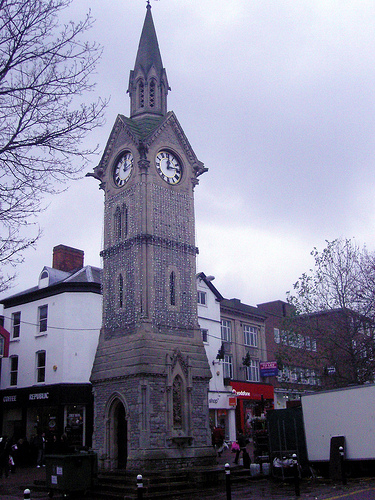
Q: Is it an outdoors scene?
A: Yes, it is outdoors.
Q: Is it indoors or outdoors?
A: It is outdoors.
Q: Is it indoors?
A: No, it is outdoors.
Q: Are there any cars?
A: No, there are no cars.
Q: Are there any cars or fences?
A: No, there are no fences or cars.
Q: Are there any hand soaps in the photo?
A: No, there are no hand soaps.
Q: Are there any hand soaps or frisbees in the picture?
A: No, there are no hand soaps or frisbees.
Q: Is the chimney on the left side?
A: Yes, the chimney is on the left of the image.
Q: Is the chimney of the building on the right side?
A: No, the chimney is on the left of the image.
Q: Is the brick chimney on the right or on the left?
A: The chimney is on the left of the image.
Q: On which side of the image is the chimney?
A: The chimney is on the left of the image.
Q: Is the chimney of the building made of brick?
A: Yes, the chimney is made of brick.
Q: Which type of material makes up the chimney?
A: The chimney is made of brick.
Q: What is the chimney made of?
A: The chimney is made of brick.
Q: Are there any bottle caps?
A: No, there are no bottle caps.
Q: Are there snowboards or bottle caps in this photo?
A: No, there are no bottle caps or snowboards.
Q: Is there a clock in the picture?
A: Yes, there is a clock.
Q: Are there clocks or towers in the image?
A: Yes, there is a clock.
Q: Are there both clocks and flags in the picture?
A: No, there is a clock but no flags.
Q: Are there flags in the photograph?
A: No, there are no flags.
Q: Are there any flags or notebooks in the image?
A: No, there are no flags or notebooks.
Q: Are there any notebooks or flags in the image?
A: No, there are no flags or notebooks.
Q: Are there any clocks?
A: Yes, there is a clock.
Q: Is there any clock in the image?
A: Yes, there is a clock.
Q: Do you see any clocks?
A: Yes, there is a clock.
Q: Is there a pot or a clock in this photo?
A: Yes, there is a clock.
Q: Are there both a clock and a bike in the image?
A: No, there is a clock but no bikes.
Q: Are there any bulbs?
A: No, there are no bulbs.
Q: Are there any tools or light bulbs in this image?
A: No, there are no light bulbs or tools.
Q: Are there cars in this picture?
A: No, there are no cars.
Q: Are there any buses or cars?
A: No, there are no cars or buses.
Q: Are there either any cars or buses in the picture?
A: No, there are no cars or buses.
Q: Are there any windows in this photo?
A: Yes, there are windows.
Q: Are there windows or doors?
A: Yes, there are windows.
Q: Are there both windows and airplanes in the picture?
A: No, there are windows but no airplanes.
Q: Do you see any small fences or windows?
A: Yes, there are small windows.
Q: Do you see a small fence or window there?
A: Yes, there are small windows.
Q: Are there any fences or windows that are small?
A: Yes, the windows are small.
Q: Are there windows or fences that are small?
A: Yes, the windows are small.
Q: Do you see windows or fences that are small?
A: Yes, the windows are small.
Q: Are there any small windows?
A: Yes, there are small windows.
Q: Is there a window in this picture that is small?
A: Yes, there are windows that are small.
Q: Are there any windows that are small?
A: Yes, there are windows that are small.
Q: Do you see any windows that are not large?
A: Yes, there are small windows.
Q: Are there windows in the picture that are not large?
A: Yes, there are small windows.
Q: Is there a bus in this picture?
A: No, there are no buses.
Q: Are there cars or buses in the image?
A: No, there are no buses or cars.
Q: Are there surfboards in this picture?
A: No, there are no surfboards.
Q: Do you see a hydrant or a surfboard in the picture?
A: No, there are no surfboards or fire hydrants.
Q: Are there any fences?
A: No, there are no fences.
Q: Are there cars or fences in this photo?
A: No, there are no fences or cars.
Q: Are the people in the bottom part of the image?
A: Yes, the people are in the bottom of the image.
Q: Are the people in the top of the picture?
A: No, the people are in the bottom of the image.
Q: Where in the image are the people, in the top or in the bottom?
A: The people are in the bottom of the image.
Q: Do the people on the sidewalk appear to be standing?
A: Yes, the people are standing.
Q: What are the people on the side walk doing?
A: The people are standing.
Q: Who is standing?
A: The people are standing.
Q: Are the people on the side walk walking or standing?
A: The people are standing.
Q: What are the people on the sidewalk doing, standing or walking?
A: The people are standing.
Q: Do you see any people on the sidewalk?
A: Yes, there are people on the sidewalk.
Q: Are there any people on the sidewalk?
A: Yes, there are people on the sidewalk.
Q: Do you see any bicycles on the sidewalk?
A: No, there are people on the sidewalk.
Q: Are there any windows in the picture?
A: Yes, there are windows.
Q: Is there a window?
A: Yes, there are windows.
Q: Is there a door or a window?
A: Yes, there are windows.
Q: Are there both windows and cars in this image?
A: No, there are windows but no cars.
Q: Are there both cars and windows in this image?
A: No, there are windows but no cars.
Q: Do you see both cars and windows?
A: No, there are windows but no cars.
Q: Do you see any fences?
A: No, there are no fences.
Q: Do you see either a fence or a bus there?
A: No, there are no fences or buses.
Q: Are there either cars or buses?
A: No, there are no cars or buses.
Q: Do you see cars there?
A: No, there are no cars.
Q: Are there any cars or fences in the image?
A: No, there are no cars or fences.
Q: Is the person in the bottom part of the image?
A: Yes, the person is in the bottom of the image.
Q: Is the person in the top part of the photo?
A: No, the person is in the bottom of the image.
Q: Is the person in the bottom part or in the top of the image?
A: The person is in the bottom of the image.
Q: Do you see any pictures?
A: No, there are no pictures.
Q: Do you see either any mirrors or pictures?
A: No, there are no pictures or mirrors.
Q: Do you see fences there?
A: No, there are no fences.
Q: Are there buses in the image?
A: No, there are no buses.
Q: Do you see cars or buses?
A: No, there are no buses or cars.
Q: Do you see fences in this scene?
A: No, there are no fences.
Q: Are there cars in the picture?
A: No, there are no cars.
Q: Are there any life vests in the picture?
A: No, there are no life vests.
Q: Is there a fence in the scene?
A: No, there are no fences.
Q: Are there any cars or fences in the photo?
A: No, there are no fences or cars.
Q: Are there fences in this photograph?
A: No, there are no fences.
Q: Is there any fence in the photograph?
A: No, there are no fences.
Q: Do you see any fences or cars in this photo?
A: No, there are no fences or cars.